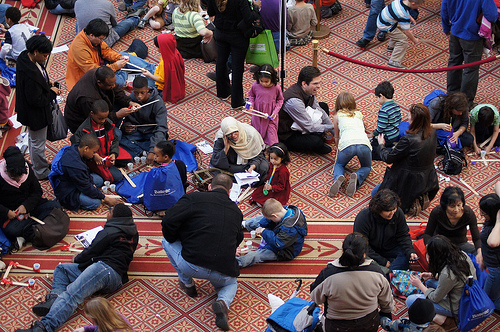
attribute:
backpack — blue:
[457, 276, 494, 328]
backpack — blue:
[431, 273, 495, 330]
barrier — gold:
[296, 37, 332, 103]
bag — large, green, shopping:
[248, 28, 284, 65]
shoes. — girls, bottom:
[320, 173, 370, 200]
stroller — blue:
[271, 279, 318, 329]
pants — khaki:
[373, 29, 411, 69]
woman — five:
[347, 183, 417, 277]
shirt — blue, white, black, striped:
[156, 190, 251, 275]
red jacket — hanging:
[157, 30, 189, 105]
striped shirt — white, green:
[171, 7, 204, 36]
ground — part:
[131, 291, 158, 313]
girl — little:
[243, 64, 287, 154]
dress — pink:
[240, 84, 285, 143]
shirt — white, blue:
[376, 2, 413, 43]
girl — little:
[244, 62, 282, 149]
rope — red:
[318, 45, 498, 75]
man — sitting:
[278, 61, 328, 152]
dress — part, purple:
[243, 81, 285, 145]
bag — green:
[241, 24, 273, 70]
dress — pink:
[250, 83, 282, 140]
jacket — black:
[81, 217, 138, 286]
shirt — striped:
[374, 0, 411, 31]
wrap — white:
[214, 117, 265, 167]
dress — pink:
[244, 86, 284, 139]